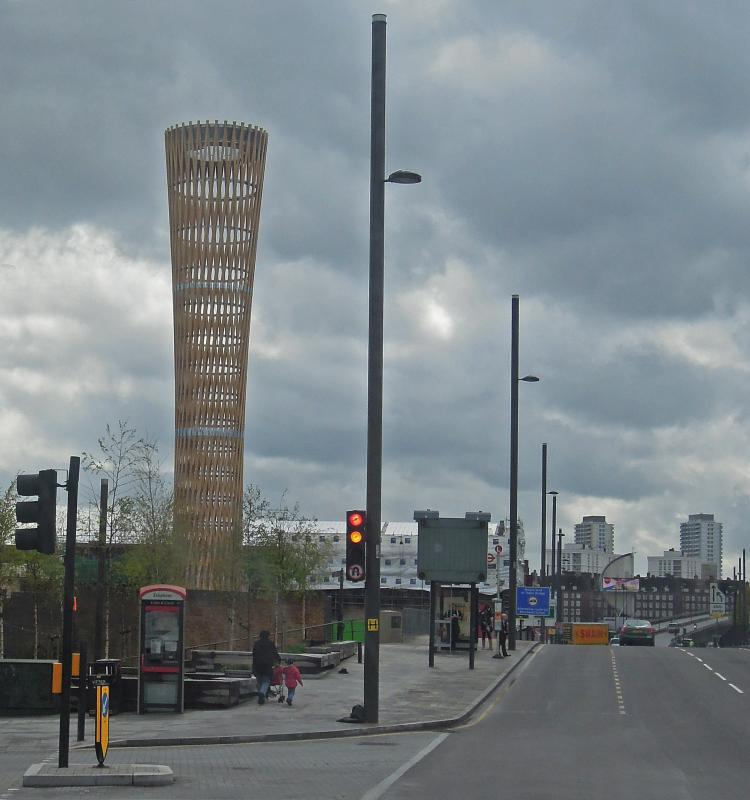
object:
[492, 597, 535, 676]
up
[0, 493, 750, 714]
building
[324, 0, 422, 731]
pole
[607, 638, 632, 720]
line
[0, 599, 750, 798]
road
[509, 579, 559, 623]
sign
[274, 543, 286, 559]
leaves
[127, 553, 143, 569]
leaves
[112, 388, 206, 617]
tree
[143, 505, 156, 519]
leaves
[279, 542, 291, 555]
leaves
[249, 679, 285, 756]
walking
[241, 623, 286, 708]
woman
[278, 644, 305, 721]
child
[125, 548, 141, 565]
leaves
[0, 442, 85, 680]
tree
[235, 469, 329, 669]
tree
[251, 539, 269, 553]
leaves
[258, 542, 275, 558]
leaves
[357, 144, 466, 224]
fixtures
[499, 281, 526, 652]
light post